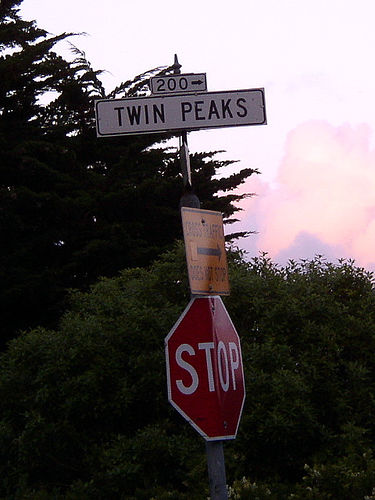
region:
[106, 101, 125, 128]
This is a letter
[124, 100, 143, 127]
This is a letter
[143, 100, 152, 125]
This is a letter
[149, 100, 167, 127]
This is a letter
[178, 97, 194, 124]
This is a letter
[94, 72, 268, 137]
small street sign stacked on top of longer one.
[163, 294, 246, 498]
stop sign nairled to a pole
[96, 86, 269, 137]
street sign with the street's name on it.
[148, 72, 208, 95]
small street sign with 200 on it.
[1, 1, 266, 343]
tree behind a pole of street signs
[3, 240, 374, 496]
big bush behind a pole of street signs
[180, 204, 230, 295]
square street sign with an arrow on it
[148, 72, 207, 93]
rectangle street sign with an arrow on it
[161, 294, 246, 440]
stop sign with red background and a white trim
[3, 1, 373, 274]
light in daytime sky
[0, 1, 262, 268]
branches of pine tree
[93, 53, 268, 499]
multiple signs on post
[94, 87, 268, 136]
rectangle sign with two words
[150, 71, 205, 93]
sign with black numbers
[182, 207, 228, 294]
sqaure sign with arrow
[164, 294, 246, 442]
red and white stop sign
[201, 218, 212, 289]
two bolts on orange sign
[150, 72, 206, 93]
sign with arrow pointing right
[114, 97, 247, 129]
black letters on white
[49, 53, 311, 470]
this is a street sign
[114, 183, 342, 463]
the signs are on a pole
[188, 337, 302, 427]
this is a stop sign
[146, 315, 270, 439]
the sign is red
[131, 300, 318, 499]
the writing is white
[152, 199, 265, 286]
the sign is yellow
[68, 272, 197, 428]
the foilage is green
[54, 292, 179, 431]
the bushes are lush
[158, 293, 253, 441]
a red STOP sign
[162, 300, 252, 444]
a red STOP sign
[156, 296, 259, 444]
a red STOP sign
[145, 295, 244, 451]
a red STOP sign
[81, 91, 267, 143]
street sign is white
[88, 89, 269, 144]
street sign is white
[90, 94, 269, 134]
street sign is white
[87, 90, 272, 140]
street sign is white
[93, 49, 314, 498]
multiple signs on a pole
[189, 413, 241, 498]
sign pole is grey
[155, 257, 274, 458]
a red sign on pole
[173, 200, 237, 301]
an orange and black sign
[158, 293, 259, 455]
a red and white sign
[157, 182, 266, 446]
a pair of sign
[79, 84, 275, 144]
a white and black sign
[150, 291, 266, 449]
red stop sign that is bent on the post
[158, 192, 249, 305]
Directional sign is above the stop sign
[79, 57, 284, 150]
street sign is above the all of the other signs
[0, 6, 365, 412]
two separate trees are behind the signs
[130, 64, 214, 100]
the 200 black of the street is to the right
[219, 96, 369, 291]
the fluffy clouds are seen behind the trees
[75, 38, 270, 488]
Many signs are on the single pole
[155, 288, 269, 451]
the stop sign is the bottom sign on the post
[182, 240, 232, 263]
the black arrow on the orange sign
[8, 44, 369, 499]
the night is setting in on the day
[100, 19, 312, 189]
signs on the pole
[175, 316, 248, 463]
sign on a metal pole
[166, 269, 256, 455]
a metal pole with sign